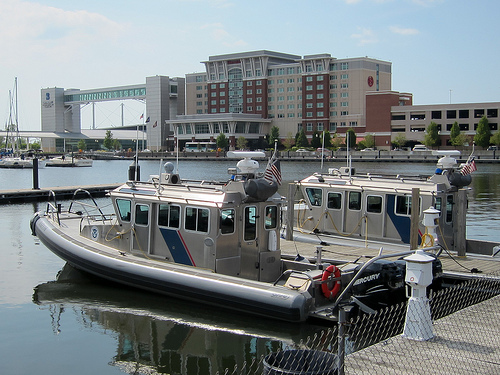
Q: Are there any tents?
A: No, there are no tents.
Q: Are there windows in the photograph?
A: Yes, there are windows.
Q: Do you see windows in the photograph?
A: Yes, there are windows.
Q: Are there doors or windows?
A: Yes, there are windows.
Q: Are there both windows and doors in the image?
A: Yes, there are both windows and a door.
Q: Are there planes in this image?
A: No, there are no planes.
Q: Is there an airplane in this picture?
A: No, there are no airplanes.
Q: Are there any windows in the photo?
A: Yes, there are windows.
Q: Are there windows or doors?
A: Yes, there are windows.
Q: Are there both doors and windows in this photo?
A: Yes, there are both windows and doors.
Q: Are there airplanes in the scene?
A: No, there are no airplanes.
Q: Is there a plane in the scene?
A: No, there are no airplanes.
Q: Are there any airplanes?
A: No, there are no airplanes.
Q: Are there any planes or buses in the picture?
A: No, there are no planes or buses.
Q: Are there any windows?
A: Yes, there are windows.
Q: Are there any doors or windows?
A: Yes, there are windows.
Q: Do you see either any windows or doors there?
A: Yes, there are windows.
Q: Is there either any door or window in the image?
A: Yes, there are windows.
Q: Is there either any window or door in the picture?
A: Yes, there are windows.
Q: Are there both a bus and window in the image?
A: No, there are windows but no buses.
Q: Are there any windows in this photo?
A: Yes, there are windows.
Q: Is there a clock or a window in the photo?
A: Yes, there are windows.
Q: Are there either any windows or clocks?
A: Yes, there are windows.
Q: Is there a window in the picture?
A: Yes, there are windows.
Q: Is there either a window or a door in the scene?
A: Yes, there are windows.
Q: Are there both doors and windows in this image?
A: Yes, there are both windows and a door.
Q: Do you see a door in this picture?
A: Yes, there is a door.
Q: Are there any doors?
A: Yes, there is a door.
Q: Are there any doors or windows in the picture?
A: Yes, there is a door.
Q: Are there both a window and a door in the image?
A: Yes, there are both a door and a window.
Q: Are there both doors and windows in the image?
A: Yes, there are both a door and a window.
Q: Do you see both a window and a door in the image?
A: Yes, there are both a door and a window.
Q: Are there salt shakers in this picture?
A: No, there are no salt shakers.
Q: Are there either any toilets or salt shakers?
A: No, there are no salt shakers or toilets.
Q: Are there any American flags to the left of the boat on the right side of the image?
A: Yes, there is an American flag to the left of the boat.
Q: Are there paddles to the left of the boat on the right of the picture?
A: No, there is an American flag to the left of the boat.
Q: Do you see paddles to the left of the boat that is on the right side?
A: No, there is an American flag to the left of the boat.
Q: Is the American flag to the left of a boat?
A: Yes, the American flag is to the left of a boat.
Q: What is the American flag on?
A: The American flag is on the boat.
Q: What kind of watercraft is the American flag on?
A: The American flag is on the boat.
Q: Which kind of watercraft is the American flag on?
A: The American flag is on the boat.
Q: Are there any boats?
A: Yes, there is a boat.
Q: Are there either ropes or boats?
A: Yes, there is a boat.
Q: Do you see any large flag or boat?
A: Yes, there is a large boat.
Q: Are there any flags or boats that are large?
A: Yes, the boat is large.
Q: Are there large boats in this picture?
A: Yes, there is a large boat.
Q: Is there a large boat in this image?
A: Yes, there is a large boat.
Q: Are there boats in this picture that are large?
A: Yes, there is a boat that is large.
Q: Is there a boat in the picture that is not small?
A: Yes, there is a large boat.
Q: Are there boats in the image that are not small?
A: Yes, there is a large boat.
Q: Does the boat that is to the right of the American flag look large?
A: Yes, the boat is large.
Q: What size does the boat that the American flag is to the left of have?
A: The boat has large size.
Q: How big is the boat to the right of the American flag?
A: The boat is large.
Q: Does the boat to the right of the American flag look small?
A: No, the boat is large.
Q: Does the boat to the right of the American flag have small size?
A: No, the boat is large.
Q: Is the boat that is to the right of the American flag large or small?
A: The boat is large.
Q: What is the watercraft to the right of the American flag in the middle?
A: The watercraft is a boat.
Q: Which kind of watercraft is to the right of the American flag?
A: The watercraft is a boat.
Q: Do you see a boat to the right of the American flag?
A: Yes, there is a boat to the right of the American flag.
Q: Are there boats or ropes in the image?
A: Yes, there is a boat.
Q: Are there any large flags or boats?
A: Yes, there is a large boat.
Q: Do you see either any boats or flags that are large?
A: Yes, the boat is large.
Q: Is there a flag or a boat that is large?
A: Yes, the boat is large.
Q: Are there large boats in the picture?
A: Yes, there is a large boat.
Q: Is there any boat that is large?
A: Yes, there is a boat that is large.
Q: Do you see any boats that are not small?
A: Yes, there is a large boat.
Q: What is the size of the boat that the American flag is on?
A: The boat is large.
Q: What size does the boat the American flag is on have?
A: The boat has large size.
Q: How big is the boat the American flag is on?
A: The boat is large.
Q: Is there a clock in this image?
A: No, there are no clocks.